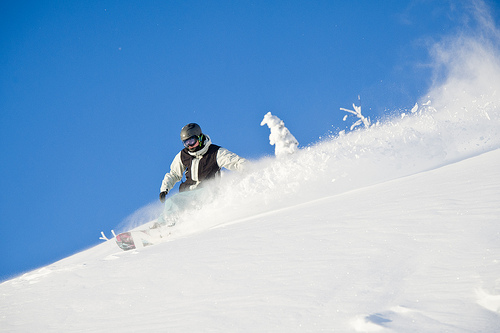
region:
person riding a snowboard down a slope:
[90, 111, 259, 252]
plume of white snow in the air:
[260, 100, 304, 162]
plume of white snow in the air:
[332, 94, 380, 136]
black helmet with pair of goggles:
[173, 117, 211, 153]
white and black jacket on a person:
[150, 134, 250, 200]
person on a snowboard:
[107, 118, 254, 255]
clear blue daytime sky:
[0, 0, 498, 281]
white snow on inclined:
[3, 94, 498, 331]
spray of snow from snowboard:
[117, 72, 497, 249]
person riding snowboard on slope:
[113, 122, 250, 251]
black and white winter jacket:
[158, 136, 251, 203]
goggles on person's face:
[181, 133, 199, 148]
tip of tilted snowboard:
[115, 223, 166, 250]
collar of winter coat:
[187, 133, 212, 158]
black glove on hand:
[157, 188, 167, 205]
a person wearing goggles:
[183, 135, 203, 153]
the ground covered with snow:
[180, 216, 412, 331]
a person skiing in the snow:
[113, 120, 238, 255]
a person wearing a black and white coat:
[155, 143, 222, 196]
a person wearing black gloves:
[157, 185, 168, 204]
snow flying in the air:
[270, 87, 472, 191]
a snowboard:
[117, 217, 162, 254]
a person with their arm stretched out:
[215, 142, 260, 184]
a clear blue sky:
[51, 35, 210, 112]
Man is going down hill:
[165, 116, 260, 282]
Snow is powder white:
[195, 205, 445, 275]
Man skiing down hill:
[125, 115, 340, 300]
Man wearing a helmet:
[170, 110, 215, 145]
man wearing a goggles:
[175, 120, 210, 150]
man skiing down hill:
[96, 122, 328, 317]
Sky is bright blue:
[30, 20, 125, 130]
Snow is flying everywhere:
[252, 100, 482, 202]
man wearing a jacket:
[157, 147, 283, 198]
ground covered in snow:
[267, 205, 453, 329]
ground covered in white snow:
[324, 195, 433, 329]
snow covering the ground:
[296, 191, 461, 331]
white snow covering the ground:
[322, 195, 466, 332]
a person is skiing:
[137, 102, 273, 242]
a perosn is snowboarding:
[128, 83, 275, 282]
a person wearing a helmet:
[150, 115, 264, 223]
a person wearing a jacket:
[169, 111, 233, 233]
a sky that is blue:
[14, 8, 368, 141]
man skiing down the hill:
[91, 99, 308, 259]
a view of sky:
[64, 46, 140, 125]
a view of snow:
[278, 209, 328, 260]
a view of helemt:
[135, 88, 233, 157]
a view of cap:
[151, 85, 241, 149]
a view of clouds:
[96, 33, 190, 91]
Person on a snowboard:
[88, 114, 268, 255]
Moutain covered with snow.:
[51, 245, 461, 312]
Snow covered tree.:
[264, 107, 304, 190]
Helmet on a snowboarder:
[176, 122, 210, 158]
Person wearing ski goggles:
[180, 137, 202, 152]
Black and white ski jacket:
[153, 145, 265, 233]